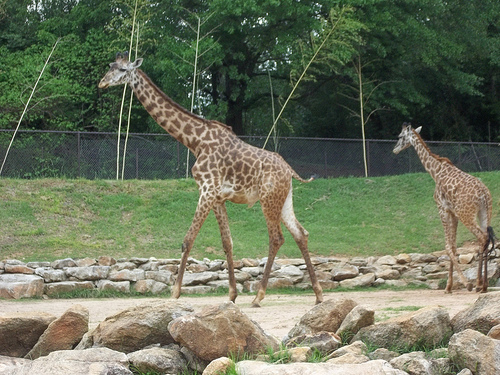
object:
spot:
[448, 179, 462, 188]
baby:
[391, 119, 494, 292]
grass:
[0, 178, 34, 196]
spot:
[247, 145, 265, 155]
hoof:
[446, 283, 455, 296]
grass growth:
[397, 338, 447, 352]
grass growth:
[423, 340, 463, 373]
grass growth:
[303, 342, 328, 363]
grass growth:
[262, 340, 297, 367]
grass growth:
[215, 355, 241, 374]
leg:
[213, 212, 240, 303]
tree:
[99, 15, 154, 181]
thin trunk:
[360, 77, 371, 179]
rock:
[442, 326, 499, 375]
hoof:
[252, 300, 262, 307]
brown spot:
[216, 181, 230, 196]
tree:
[166, 0, 322, 144]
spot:
[144, 84, 158, 100]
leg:
[282, 191, 326, 307]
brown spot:
[218, 147, 233, 160]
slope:
[3, 166, 498, 266]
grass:
[75, 227, 112, 247]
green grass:
[478, 175, 500, 198]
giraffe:
[95, 53, 324, 310]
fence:
[0, 126, 500, 178]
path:
[2, 287, 487, 317]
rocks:
[1, 343, 117, 374]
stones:
[96, 279, 136, 295]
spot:
[134, 88, 142, 95]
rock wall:
[0, 242, 497, 297]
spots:
[446, 201, 451, 207]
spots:
[451, 178, 457, 185]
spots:
[428, 162, 437, 168]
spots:
[462, 221, 470, 228]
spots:
[434, 165, 442, 174]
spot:
[183, 135, 200, 150]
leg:
[212, 208, 242, 305]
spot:
[273, 188, 298, 202]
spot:
[269, 201, 283, 215]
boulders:
[0, 293, 284, 373]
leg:
[171, 192, 217, 302]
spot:
[182, 124, 194, 135]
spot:
[460, 206, 472, 214]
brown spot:
[221, 167, 236, 177]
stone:
[339, 271, 376, 290]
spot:
[141, 79, 153, 84]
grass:
[389, 174, 425, 205]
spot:
[422, 154, 439, 168]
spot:
[214, 123, 236, 136]